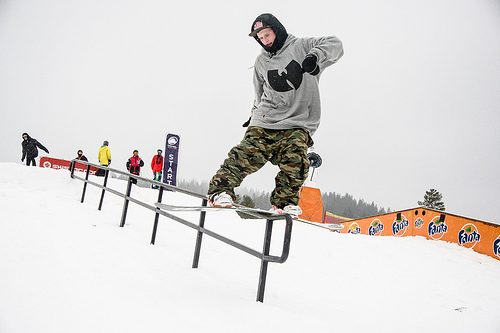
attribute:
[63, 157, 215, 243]
railing — metal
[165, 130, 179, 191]
sign — purple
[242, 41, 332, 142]
hoodie — black, grey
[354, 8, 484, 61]
sky — grey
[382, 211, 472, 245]
sign — orange